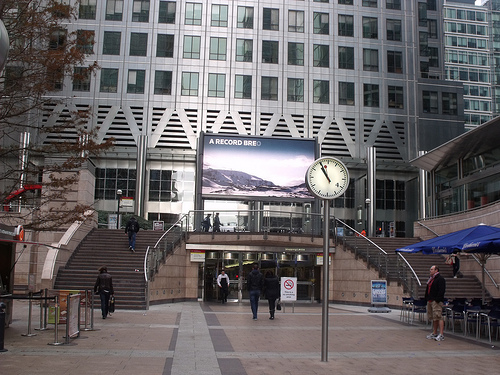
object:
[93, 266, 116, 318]
people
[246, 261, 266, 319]
people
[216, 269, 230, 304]
people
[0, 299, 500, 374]
place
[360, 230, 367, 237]
orange jacket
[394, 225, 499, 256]
blue umbrella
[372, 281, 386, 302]
logo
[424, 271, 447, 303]
shirt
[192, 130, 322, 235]
billboard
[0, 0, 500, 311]
building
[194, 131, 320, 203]
sign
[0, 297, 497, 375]
ground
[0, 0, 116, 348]
trees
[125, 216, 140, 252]
person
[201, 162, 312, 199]
mountains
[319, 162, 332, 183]
hand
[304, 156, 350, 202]
clock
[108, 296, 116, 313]
briefcase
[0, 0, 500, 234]
windows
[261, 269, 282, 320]
people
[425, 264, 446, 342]
man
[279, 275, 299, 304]
sign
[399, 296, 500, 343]
chairs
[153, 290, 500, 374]
walkway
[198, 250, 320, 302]
door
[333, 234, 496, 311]
stairs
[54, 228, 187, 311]
staircase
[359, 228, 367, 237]
person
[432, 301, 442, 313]
pocket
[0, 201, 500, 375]
area